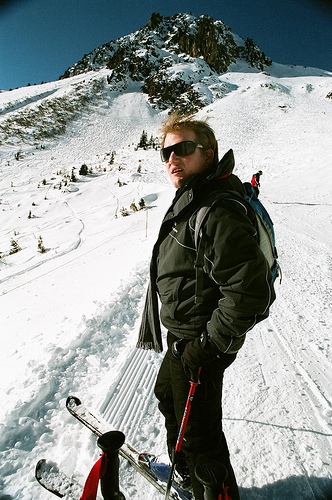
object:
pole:
[161, 382, 201, 500]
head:
[161, 121, 214, 188]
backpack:
[229, 182, 282, 285]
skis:
[35, 392, 185, 496]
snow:
[17, 64, 112, 159]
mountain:
[40, 10, 332, 227]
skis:
[34, 454, 174, 499]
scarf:
[136, 179, 202, 353]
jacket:
[154, 150, 275, 354]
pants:
[154, 334, 242, 492]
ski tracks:
[87, 334, 162, 461]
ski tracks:
[1, 191, 85, 283]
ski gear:
[136, 147, 282, 498]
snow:
[52, 253, 131, 344]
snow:
[14, 424, 73, 483]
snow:
[245, 428, 324, 499]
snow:
[277, 226, 330, 285]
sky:
[19, 12, 61, 77]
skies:
[34, 9, 129, 180]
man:
[155, 113, 275, 500]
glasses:
[160, 140, 204, 162]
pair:
[154, 328, 242, 500]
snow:
[6, 125, 44, 232]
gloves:
[181, 330, 223, 382]